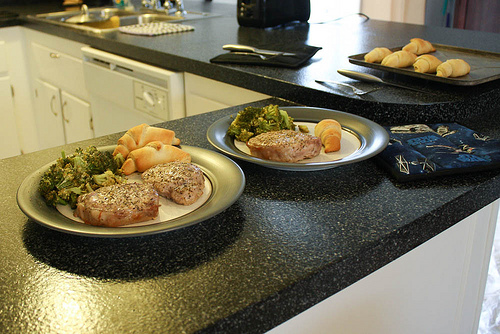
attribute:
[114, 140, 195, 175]
roll — golden, brown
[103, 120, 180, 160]
roll — golden, brown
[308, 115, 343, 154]
roll — golden, brown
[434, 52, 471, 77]
roll — golden, brown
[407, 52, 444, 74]
roll — golden, brown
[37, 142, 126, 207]
broccoli — green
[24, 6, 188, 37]
sink — stainless steel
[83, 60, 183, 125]
dish washer — white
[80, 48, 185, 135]
dishwasher — white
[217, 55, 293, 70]
napkin — black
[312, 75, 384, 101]
fork — silver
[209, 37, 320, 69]
napkin — black